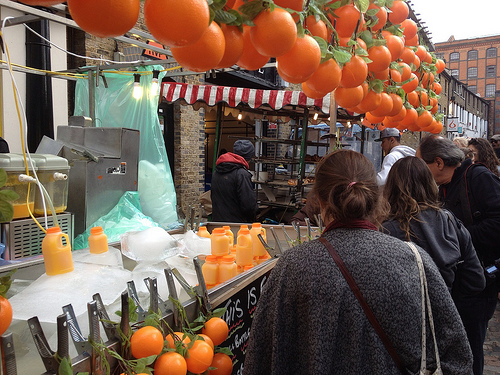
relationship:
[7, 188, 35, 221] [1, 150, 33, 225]
juice in container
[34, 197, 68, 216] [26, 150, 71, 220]
juice in container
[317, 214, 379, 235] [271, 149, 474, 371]
collar of woman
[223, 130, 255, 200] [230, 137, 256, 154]
man wearing hat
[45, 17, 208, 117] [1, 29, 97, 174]
conditioner in window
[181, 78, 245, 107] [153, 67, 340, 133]
stripe on canopy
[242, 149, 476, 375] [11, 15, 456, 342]
female at shopping center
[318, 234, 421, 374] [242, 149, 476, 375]
purse strap on female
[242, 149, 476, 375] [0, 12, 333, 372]
female patronizing business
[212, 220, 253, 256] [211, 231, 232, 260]
jug has orange juice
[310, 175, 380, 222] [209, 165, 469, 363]
hair of woman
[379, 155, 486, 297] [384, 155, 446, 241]
people wearing hair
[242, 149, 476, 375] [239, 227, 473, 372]
female wearing sweater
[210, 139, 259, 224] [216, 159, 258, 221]
man in a coat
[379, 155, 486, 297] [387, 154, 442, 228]
people with hair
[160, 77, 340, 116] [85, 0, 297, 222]
awning on building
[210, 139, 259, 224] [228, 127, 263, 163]
man with hat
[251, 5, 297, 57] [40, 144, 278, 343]
orange on side of truck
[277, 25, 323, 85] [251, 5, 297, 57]
oranges on side of orange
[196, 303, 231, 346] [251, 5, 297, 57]
oranges on side of orange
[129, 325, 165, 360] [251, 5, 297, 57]
orange on side of orange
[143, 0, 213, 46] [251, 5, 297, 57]
oranges on side of orange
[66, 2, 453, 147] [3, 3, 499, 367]
oranges on side of truck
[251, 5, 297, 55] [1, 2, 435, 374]
orange on side of truck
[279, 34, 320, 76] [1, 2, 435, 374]
orange on side of truck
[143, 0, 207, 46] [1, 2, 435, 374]
orange on side of truck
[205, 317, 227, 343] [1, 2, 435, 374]
orange on side of truck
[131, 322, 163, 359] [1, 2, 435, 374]
orange on side of truck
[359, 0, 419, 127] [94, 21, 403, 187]
oranges on side of truck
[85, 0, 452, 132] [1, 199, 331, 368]
oranges on truck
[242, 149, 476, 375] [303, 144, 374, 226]
female had head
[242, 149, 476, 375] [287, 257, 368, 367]
female has back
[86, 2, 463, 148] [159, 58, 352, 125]
decorative ranges hanging from canopy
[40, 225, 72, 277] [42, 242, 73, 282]
orange juice in jug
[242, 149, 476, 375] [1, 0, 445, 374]
female walking by stall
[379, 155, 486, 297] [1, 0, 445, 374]
people walking by stall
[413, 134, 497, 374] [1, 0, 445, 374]
people walking by stall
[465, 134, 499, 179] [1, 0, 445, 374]
person walking by stall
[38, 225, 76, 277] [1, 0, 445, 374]
orange juice walking by stall